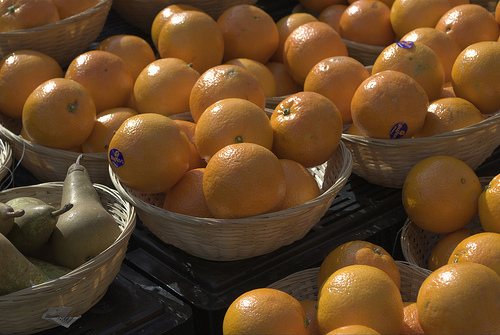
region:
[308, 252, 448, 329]
shiny and smooth oranges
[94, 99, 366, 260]
lots of oranges on a basket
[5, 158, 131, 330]
pears on a basket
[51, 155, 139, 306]
gray shiny pear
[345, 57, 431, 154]
orange with a blue sticker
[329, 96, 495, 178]
light colored fruit basket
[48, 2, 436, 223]
piles of oranges on baskets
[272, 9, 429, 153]
sun is shinning on orange skin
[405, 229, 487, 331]
oranges reflecting sun light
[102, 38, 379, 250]
ready to eat oranges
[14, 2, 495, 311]
baskets of fruit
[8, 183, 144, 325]
a basket of pears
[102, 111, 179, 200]
an orange with a sticker on it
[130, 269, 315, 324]
black crates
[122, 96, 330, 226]
shiny fresh oranges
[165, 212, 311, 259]
a wicker basket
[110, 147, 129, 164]
a blue and orange produce sticker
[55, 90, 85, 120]
an orange stem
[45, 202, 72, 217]
the stem on a pear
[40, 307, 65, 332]
a stray, white sticker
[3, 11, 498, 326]
bowls of oranges in the sunlight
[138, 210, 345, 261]
tan wicker basket holding oranges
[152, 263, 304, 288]
black table oranges are on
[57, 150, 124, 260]
brown pear with stem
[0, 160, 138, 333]
wicker bowl of pears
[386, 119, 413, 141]
blue sticker label on an orange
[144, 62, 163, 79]
sunlight on an orange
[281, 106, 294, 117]
part of orange where it was attached to tree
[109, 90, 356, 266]
wicker bowl with eight oranges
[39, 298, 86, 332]
white label on wicker basket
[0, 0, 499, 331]
Oranges and pears baskets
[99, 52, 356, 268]
Basket has 8 oranges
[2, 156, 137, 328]
Basket with green pears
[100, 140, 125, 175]
Blue sticker on orange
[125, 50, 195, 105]
Sun reflection on orange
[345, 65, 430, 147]
Orange with blue sticker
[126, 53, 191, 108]
Sun reflects on orange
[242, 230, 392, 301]
Shadow cast on oranges.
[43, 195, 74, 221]
Stick of pear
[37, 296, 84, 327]
Piece of paper on basket.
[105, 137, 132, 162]
The orange has a blue sticker.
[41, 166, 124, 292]
Pears sitting in the basket.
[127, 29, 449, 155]
Tons of oranges in baskets.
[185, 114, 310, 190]
The oranges are orange.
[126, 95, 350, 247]
the oranges are sitting in the basket.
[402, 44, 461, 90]
One orange is not that ripe.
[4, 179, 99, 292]
The pears look too ripe.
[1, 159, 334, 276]
Oranges and pears sitting on boxed crates.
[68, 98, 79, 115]
The stem of the orange is green.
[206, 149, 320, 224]
The oranges are round